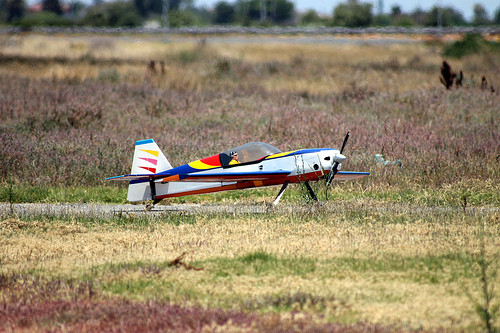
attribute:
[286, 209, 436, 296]
grass — dry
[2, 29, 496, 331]
grass — dry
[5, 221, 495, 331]
grass — dry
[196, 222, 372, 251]
grass — Dry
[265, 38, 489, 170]
grass — dry